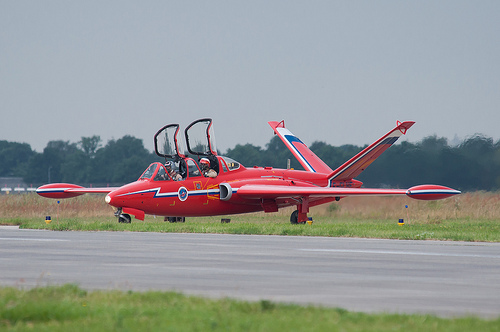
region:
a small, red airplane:
[30, 70, 497, 299]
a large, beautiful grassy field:
[6, 167, 497, 256]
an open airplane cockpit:
[181, 111, 225, 188]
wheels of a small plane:
[274, 199, 319, 244]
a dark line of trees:
[20, 108, 498, 219]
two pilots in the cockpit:
[122, 117, 242, 195]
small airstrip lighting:
[27, 204, 62, 236]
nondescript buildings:
[6, 168, 83, 210]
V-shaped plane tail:
[257, 100, 427, 207]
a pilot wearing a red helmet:
[191, 148, 219, 177]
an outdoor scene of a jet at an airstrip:
[0, 0, 497, 330]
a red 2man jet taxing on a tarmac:
[35, 118, 460, 231]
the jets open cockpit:
[140, 118, 242, 178]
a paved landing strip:
[0, 225, 499, 318]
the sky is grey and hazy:
[1, 1, 498, 120]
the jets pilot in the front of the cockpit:
[160, 161, 181, 180]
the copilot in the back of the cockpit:
[195, 156, 215, 178]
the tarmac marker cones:
[43, 213, 51, 223]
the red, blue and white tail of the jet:
[267, 118, 414, 175]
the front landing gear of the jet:
[115, 204, 132, 225]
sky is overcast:
[0, 4, 495, 144]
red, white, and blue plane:
[1, 114, 467, 244]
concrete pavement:
[2, 207, 497, 316]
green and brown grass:
[0, 159, 499, 234]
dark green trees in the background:
[2, 127, 493, 189]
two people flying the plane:
[142, 112, 250, 222]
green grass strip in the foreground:
[0, 279, 493, 329]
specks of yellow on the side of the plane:
[179, 177, 241, 216]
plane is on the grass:
[28, 110, 463, 249]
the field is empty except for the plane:
[6, 107, 498, 327]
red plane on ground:
[66, 91, 436, 268]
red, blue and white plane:
[109, 105, 407, 270]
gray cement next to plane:
[180, 244, 277, 288]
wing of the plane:
[353, 169, 445, 226]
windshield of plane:
[150, 105, 232, 157]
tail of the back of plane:
[276, 100, 418, 187]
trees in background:
[64, 112, 126, 167]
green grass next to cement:
[79, 288, 145, 328]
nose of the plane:
[89, 183, 136, 230]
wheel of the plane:
[283, 203, 322, 233]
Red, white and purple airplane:
[30, 110, 465, 225]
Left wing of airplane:
[232, 181, 462, 202]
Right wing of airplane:
[30, 175, 130, 200]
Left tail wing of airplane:
[332, 115, 412, 180]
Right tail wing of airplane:
[262, 115, 332, 172]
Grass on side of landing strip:
[3, 281, 463, 326]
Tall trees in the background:
[2, 128, 142, 179]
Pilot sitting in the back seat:
[195, 150, 220, 175]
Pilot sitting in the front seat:
[153, 155, 183, 176]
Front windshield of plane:
[131, 158, 171, 182]